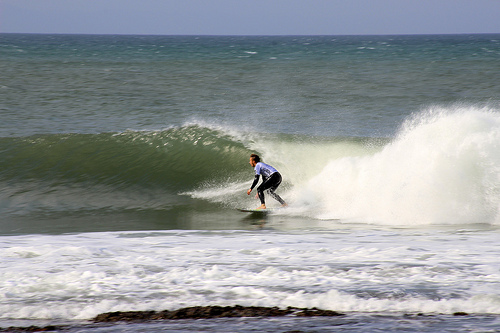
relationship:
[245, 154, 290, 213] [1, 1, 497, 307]
surfer on ocean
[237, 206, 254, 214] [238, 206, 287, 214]
nose of a board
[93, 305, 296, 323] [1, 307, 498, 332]
rock on beach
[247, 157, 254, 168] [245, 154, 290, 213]
face of surfer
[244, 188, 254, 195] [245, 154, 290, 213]
hand of surfer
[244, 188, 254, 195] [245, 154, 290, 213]
hand on surfer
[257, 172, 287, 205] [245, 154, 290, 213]
pants on surfer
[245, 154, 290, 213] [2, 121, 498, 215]
surfer on wave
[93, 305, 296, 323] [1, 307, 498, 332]
rock near beach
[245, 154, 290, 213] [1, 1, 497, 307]
surfer in ocean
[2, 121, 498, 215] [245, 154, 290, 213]
wave behind surfer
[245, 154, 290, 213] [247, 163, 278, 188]
surfer has on shirt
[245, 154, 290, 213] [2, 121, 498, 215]
surfer by wave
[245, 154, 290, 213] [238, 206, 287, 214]
surfer on board